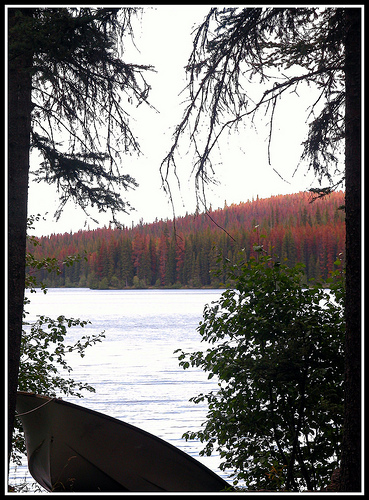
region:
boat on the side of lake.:
[56, 398, 160, 468]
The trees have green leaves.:
[233, 302, 316, 393]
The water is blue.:
[100, 279, 180, 348]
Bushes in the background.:
[122, 234, 188, 270]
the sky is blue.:
[50, 223, 71, 229]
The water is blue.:
[123, 299, 163, 339]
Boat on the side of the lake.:
[54, 404, 144, 472]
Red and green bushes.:
[199, 213, 257, 237]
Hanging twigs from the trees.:
[163, 145, 251, 237]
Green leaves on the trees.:
[227, 280, 318, 384]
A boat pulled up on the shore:
[15, 390, 234, 491]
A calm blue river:
[40, 276, 286, 485]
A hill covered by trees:
[43, 180, 336, 296]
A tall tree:
[245, 8, 361, 482]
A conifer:
[119, 240, 135, 289]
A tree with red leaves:
[157, 231, 167, 281]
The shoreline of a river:
[26, 270, 348, 302]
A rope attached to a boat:
[13, 393, 55, 424]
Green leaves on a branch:
[34, 314, 94, 328]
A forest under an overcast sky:
[36, 161, 312, 299]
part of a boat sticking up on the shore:
[16, 388, 242, 493]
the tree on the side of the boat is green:
[170, 209, 349, 491]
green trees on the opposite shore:
[133, 275, 148, 289]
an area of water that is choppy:
[120, 306, 195, 350]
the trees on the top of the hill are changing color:
[280, 190, 341, 221]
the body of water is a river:
[30, 286, 342, 428]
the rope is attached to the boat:
[1, 398, 58, 424]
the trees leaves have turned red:
[272, 192, 343, 229]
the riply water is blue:
[121, 313, 213, 350]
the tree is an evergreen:
[28, 6, 171, 235]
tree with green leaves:
[11, 16, 129, 215]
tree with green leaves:
[14, 310, 83, 389]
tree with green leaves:
[216, 273, 325, 464]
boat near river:
[19, 402, 200, 490]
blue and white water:
[100, 295, 171, 402]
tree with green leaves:
[204, 19, 347, 188]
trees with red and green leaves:
[45, 241, 162, 280]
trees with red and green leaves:
[142, 229, 217, 282]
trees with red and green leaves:
[222, 204, 294, 248]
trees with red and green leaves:
[295, 199, 337, 267]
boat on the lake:
[14, 391, 243, 486]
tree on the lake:
[223, 284, 335, 485]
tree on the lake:
[8, 281, 105, 469]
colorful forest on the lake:
[149, 195, 333, 273]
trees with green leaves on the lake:
[27, 190, 338, 269]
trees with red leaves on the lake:
[101, 219, 342, 281]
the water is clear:
[23, 282, 329, 487]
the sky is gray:
[25, 2, 345, 234]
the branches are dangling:
[27, 124, 131, 211]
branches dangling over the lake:
[198, 19, 343, 105]